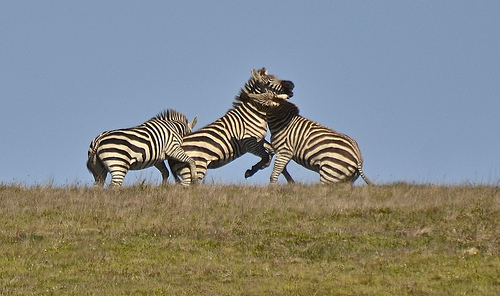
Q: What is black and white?
A: The zebras.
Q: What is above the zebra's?
A: The blue sky.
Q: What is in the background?
A: The zebras.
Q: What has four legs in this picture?
A: The zebra's.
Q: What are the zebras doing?
A: Fighting.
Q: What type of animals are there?
A: Zebra.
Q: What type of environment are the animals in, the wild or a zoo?
A: The wild.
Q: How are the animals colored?
A: Black and white.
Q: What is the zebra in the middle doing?
A: Jumping up on its hind legs.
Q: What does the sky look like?
A: Blue gray.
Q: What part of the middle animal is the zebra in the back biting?
A: Its rump.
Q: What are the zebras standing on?
A: Grass.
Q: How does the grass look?
A: Green and brown.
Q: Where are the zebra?
A: In the wild.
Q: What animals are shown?
A: Zebras.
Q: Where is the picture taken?
A: The bush.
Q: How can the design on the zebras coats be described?
A: Striped.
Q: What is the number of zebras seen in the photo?
A: 3.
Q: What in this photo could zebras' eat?
A: Grass.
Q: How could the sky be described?
A: Blue and clear.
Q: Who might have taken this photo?
A: Wildlife photographer.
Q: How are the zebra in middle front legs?
A: In air.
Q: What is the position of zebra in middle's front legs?
A: Bent.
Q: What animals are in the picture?
A: Zebras.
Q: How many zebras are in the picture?
A: Three.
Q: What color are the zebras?
A: White and black.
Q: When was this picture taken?
A: During the day.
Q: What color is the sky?
A: Blue.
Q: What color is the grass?
A: Green.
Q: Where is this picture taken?
A: In a field.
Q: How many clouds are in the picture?
A: Zero.